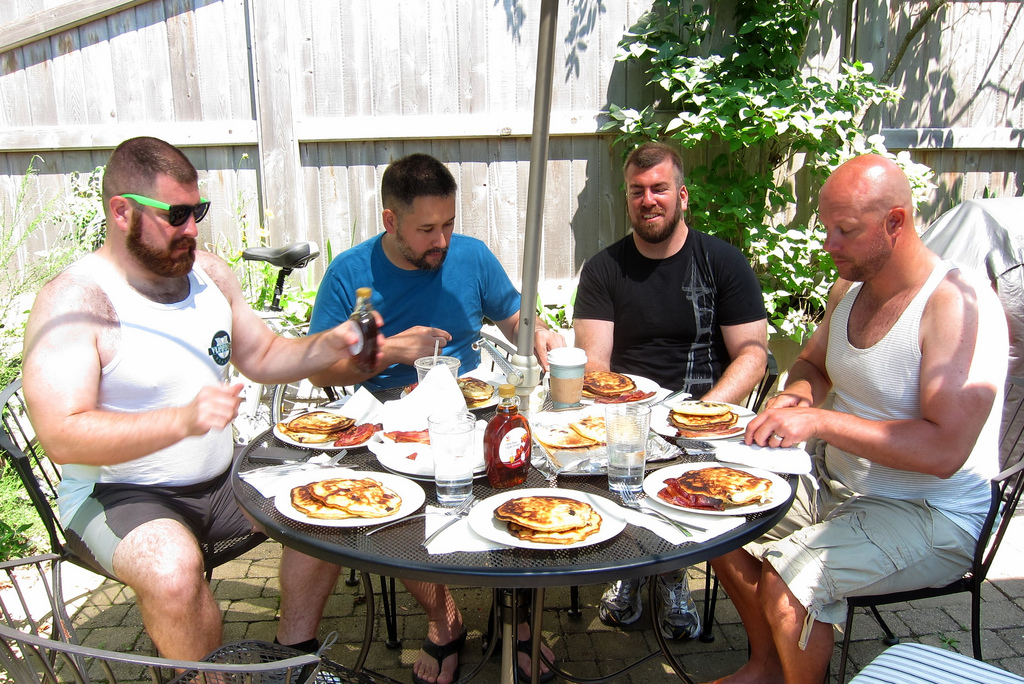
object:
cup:
[547, 347, 588, 410]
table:
[228, 382, 798, 684]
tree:
[603, 0, 934, 358]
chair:
[0, 379, 377, 684]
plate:
[643, 461, 793, 515]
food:
[659, 467, 774, 511]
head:
[818, 155, 914, 283]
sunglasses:
[121, 193, 211, 226]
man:
[309, 152, 563, 684]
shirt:
[309, 232, 522, 390]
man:
[709, 153, 1008, 684]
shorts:
[740, 444, 1003, 650]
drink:
[605, 404, 651, 491]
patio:
[0, 0, 1024, 684]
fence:
[0, 0, 1024, 308]